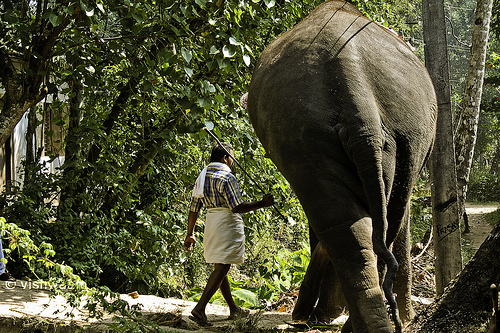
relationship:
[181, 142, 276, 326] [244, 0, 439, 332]
man controlling an elephant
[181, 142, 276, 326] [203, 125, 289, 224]
man holding stick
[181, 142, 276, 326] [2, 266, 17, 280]
man has shoe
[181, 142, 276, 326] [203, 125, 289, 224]
man carrying stick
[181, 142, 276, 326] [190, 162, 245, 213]
man wearing plaid shirt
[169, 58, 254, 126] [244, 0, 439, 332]
trees around elephant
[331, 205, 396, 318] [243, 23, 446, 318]
foot of elephant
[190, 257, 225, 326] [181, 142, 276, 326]
leg of man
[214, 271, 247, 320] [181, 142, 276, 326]
leg of man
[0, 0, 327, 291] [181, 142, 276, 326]
leaves near man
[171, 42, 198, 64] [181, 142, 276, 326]
leaves near man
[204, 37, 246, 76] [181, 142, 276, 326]
leaves near man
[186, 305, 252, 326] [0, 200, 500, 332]
feet on ground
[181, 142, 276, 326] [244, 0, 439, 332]
man guiding elephant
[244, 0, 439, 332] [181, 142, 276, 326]
elephant with man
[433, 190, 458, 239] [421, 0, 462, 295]
writing on pole